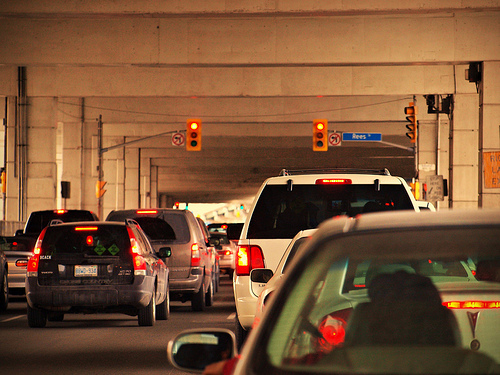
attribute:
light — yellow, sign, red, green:
[174, 100, 211, 155]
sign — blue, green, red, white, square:
[337, 125, 381, 146]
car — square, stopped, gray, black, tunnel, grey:
[312, 237, 427, 319]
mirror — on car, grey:
[156, 320, 232, 362]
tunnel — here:
[13, 131, 161, 198]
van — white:
[263, 173, 312, 180]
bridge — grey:
[161, 33, 243, 86]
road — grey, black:
[51, 330, 91, 338]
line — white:
[82, 323, 116, 333]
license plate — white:
[60, 256, 103, 278]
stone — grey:
[71, 44, 123, 71]